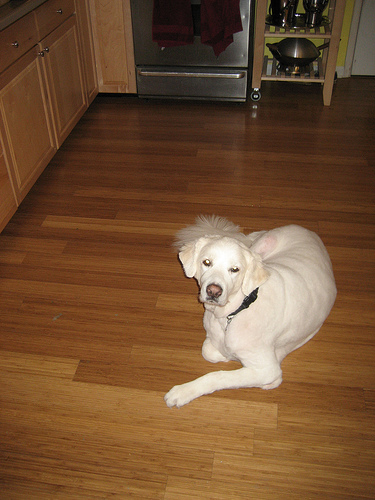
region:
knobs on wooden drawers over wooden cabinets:
[1, 1, 96, 217]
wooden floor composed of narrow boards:
[0, 87, 367, 342]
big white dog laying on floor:
[154, 206, 336, 405]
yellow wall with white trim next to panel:
[255, 0, 371, 80]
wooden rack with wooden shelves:
[246, 0, 340, 100]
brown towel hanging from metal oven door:
[125, 0, 247, 100]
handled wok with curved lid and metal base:
[258, 32, 335, 72]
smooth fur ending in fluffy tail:
[157, 210, 338, 407]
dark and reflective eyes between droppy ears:
[175, 236, 269, 296]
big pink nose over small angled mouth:
[195, 277, 228, 305]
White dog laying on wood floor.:
[163, 215, 334, 405]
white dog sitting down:
[157, 194, 343, 414]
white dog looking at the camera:
[146, 201, 332, 433]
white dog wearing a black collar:
[160, 225, 267, 327]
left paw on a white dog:
[149, 366, 260, 419]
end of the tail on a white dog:
[171, 208, 272, 253]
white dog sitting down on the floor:
[139, 186, 351, 412]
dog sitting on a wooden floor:
[157, 215, 338, 417]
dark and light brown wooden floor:
[53, 181, 158, 475]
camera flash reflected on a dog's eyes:
[195, 251, 243, 279]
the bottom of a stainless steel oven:
[127, 9, 254, 109]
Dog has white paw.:
[151, 376, 196, 418]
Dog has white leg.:
[192, 368, 237, 388]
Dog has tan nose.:
[206, 283, 230, 304]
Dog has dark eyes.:
[195, 255, 243, 277]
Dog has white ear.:
[242, 252, 271, 297]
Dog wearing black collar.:
[235, 287, 254, 303]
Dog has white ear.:
[180, 252, 200, 273]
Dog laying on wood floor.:
[165, 301, 270, 403]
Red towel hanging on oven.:
[160, 11, 206, 54]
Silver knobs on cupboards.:
[35, 40, 58, 58]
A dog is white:
[161, 208, 337, 411]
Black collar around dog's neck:
[218, 279, 263, 320]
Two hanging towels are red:
[146, 0, 242, 60]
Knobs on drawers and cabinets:
[2, 4, 65, 60]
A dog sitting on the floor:
[0, 93, 369, 493]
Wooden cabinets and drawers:
[0, 0, 95, 231]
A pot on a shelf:
[259, 33, 326, 85]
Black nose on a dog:
[199, 274, 220, 300]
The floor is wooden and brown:
[0, 75, 368, 495]